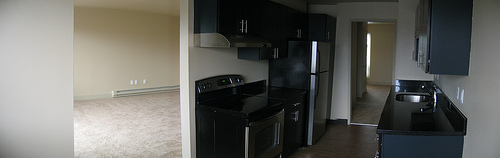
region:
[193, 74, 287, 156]
Black stove in kitchen.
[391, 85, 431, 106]
Sink on top of kitchen counter.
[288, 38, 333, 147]
Black and stainless steel refrigerator.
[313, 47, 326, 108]
Handles on refrigerator doors.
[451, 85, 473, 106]
Electrical outlets on wall.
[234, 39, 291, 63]
Hood vent mounted over stove.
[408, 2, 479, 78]
Cabinets mounted on kitchen wall.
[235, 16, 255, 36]
Handles on cabinet doors.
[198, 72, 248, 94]
Control knobs back of stove.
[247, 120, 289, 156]
Window on oven door.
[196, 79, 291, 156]
a black and silver stove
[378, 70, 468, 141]
a long black counter top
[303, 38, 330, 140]
a silver refrigerator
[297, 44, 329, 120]
a refrigerator with black handles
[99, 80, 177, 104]
a white wall heater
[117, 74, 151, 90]
white electrical outlets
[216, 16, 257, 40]
black cabinets with silver handles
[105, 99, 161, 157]
carpeting on the floor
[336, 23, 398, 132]
a hallway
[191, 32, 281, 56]
a silver oven hood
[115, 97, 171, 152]
Beige carpet on the floor.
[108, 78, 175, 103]
Baseboard heat in the room.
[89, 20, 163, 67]
Bare beige wall in the room.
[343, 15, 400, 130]
Hallway leading to other rooms.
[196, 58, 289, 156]
Silver stove in the kitchen.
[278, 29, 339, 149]
Silver fridge in the kitchen.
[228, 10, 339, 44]
Cabinets on the wall.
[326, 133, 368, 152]
Wood floor in the kitchen.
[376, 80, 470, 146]
Shiny black counter top.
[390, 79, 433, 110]
Shiny silver sink in the kitchen.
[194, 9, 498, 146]
photo of a brand new kitchen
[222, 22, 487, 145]
photo of a brand new black kitchen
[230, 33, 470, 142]
photo of a brand new kitchen in new house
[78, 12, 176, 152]
photo of brand new living room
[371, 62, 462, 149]
black kitchen sink and counter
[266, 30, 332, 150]
stainless steel fridge in kitchen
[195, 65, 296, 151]
stove in a new kitchen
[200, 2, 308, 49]
black kitchen cabinets in new kitchen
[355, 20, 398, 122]
doorway in a brand new kitchen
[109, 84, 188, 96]
white floor heating vent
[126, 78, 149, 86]
white standard electrical outlets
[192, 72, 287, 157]
black and chrome stovetop and oven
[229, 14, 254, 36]
chrome handles on black cabinet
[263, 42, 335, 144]
chrome and black refrigerator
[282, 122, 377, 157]
dark brown wooden floor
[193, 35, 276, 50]
chrome range vent top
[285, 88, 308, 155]
black cabinet front with chrome handles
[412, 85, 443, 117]
chrome sink faucet fixtures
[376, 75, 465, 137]
black granite countertops